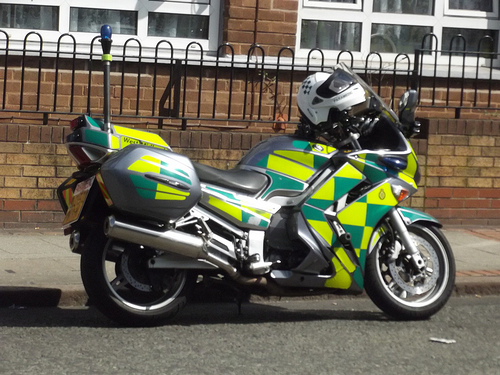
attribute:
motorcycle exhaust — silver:
[95, 209, 228, 267]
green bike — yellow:
[64, 101, 483, 294]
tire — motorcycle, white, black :
[79, 215, 196, 326]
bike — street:
[99, 83, 461, 320]